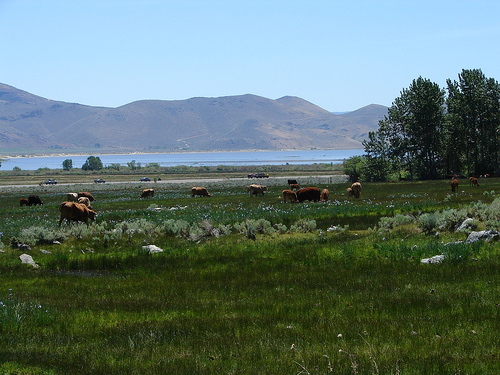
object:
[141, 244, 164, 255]
rock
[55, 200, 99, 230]
cows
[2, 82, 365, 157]
hills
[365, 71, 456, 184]
trees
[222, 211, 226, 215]
flowers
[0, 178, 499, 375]
field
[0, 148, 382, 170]
lake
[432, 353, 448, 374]
grass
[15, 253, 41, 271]
rocks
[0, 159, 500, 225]
pasture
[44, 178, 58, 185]
cars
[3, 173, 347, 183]
road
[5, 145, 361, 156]
shore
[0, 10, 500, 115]
sky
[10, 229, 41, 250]
scrub brush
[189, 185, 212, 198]
cow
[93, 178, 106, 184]
car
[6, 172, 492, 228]
cattle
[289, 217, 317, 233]
plants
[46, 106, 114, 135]
there is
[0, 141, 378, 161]
base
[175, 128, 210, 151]
path